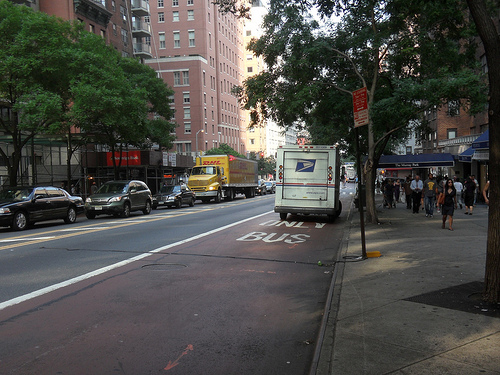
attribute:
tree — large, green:
[93, 53, 177, 195]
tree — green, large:
[217, 3, 497, 225]